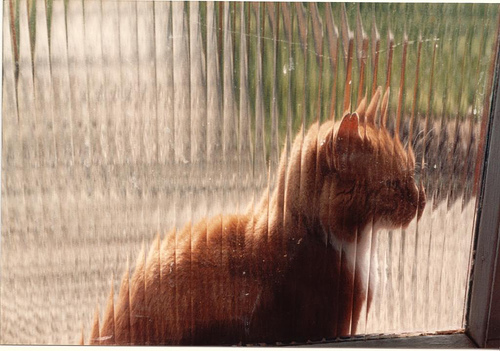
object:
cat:
[81, 107, 426, 344]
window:
[0, 0, 499, 346]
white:
[327, 230, 377, 291]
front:
[343, 228, 374, 335]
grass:
[188, 0, 481, 193]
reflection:
[328, 32, 431, 147]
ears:
[355, 85, 390, 127]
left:
[465, 0, 500, 351]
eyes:
[385, 179, 400, 190]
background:
[3, 0, 499, 199]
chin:
[380, 214, 414, 230]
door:
[466, 45, 499, 349]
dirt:
[385, 117, 479, 196]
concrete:
[0, 1, 229, 344]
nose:
[415, 201, 426, 207]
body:
[82, 214, 372, 347]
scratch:
[184, 19, 444, 61]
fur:
[319, 174, 373, 237]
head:
[285, 87, 427, 231]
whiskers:
[384, 204, 414, 230]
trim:
[309, 330, 498, 349]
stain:
[476, 48, 483, 196]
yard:
[186, 2, 499, 162]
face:
[382, 160, 425, 210]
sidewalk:
[51, 1, 217, 161]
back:
[156, 215, 252, 248]